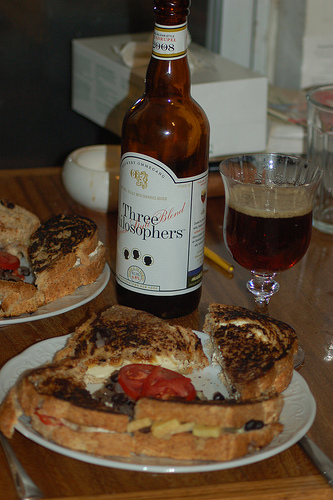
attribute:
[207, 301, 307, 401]
bread — toasted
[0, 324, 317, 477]
plate — full, white, round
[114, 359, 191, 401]
tomato — red, sliced, slice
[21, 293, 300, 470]
sandwich — brown, sliced, browned, delicious, cut into pieces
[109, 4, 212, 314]
bottle — wine, large, beverage bottle, tall, brown, beer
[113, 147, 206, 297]
label — white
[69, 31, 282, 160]
box — white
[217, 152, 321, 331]
glass — fluted, stemmed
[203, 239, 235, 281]
pencil — yellow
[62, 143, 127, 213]
dish — white, small, little, round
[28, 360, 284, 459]
half — grilled